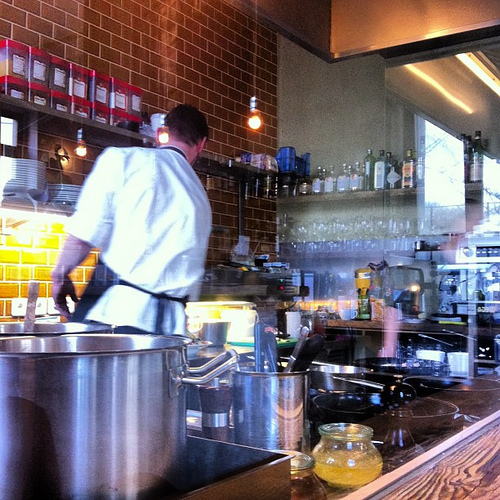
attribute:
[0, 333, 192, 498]
steel pot — large stainless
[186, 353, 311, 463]
stainless container — small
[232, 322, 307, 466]
small container — with utensils in it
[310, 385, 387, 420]
frying pan — on counter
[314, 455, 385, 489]
liquid — yellow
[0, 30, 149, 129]
containers — clear, spice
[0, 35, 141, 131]
lids — red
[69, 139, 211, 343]
tshirt — white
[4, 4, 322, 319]
wall — brick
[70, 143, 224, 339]
shirt — white, chef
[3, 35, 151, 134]
containers — red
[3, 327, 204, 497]
pot — large, silver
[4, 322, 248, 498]
pot — silver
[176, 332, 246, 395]
handle — large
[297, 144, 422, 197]
bottles — oil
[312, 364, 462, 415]
pans — black, frying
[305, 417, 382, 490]
container — glass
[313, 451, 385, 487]
liquid — yellow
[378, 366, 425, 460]
grinder — black pepper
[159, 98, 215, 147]
hair — short, dark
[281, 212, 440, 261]
glasses — many, empty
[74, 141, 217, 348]
shirt — white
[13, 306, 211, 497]
pots — many, large, metal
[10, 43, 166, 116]
containers — many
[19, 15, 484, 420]
area — kitchen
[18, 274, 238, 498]
pot — large, metal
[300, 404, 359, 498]
liquid — yellow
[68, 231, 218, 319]
apron — black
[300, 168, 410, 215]
shelf — top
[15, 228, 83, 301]
wall — yellow, brick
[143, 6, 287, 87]
bricks — red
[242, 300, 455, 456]
items — lot of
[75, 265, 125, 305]
apron — black, chef